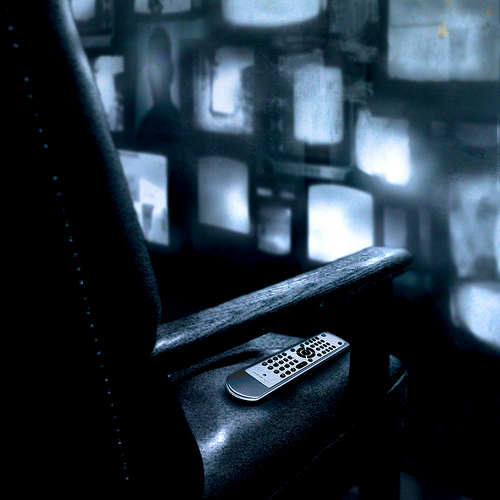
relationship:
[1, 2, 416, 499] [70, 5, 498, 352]
chair facing monitors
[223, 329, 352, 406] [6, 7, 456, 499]
remote on chair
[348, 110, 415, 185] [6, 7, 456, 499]
screen by chair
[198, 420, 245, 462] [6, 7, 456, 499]
reflection on chair